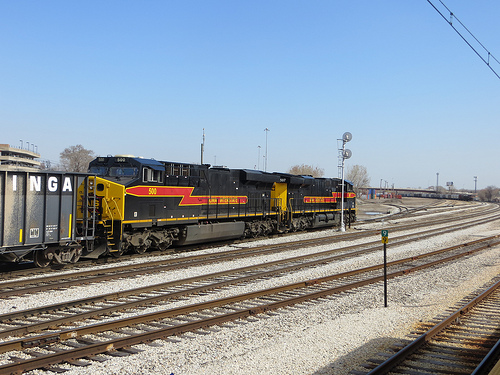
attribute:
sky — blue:
[1, 1, 499, 195]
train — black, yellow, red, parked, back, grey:
[1, 142, 356, 270]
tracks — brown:
[3, 196, 500, 372]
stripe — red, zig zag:
[129, 182, 253, 209]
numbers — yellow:
[144, 184, 158, 200]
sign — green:
[381, 230, 391, 235]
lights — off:
[91, 157, 136, 164]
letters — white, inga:
[12, 171, 77, 195]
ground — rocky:
[234, 331, 370, 366]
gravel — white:
[318, 300, 368, 330]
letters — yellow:
[208, 193, 242, 206]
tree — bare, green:
[346, 162, 369, 202]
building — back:
[0, 142, 42, 170]